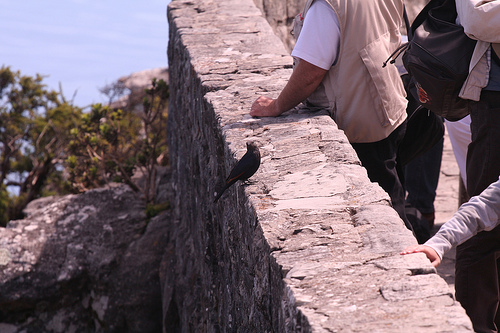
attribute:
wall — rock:
[382, 221, 445, 281]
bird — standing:
[201, 136, 276, 216]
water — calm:
[2, 0, 172, 105]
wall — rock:
[166, 17, 261, 316]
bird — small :
[189, 142, 278, 202]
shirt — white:
[291, 11, 346, 71]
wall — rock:
[165, 36, 302, 324]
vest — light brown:
[307, 7, 414, 134]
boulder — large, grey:
[19, 144, 170, 309]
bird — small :
[209, 138, 261, 205]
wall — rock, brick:
[161, 2, 498, 332]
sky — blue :
[3, 4, 165, 204]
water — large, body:
[0, 8, 158, 108]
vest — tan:
[311, 1, 410, 144]